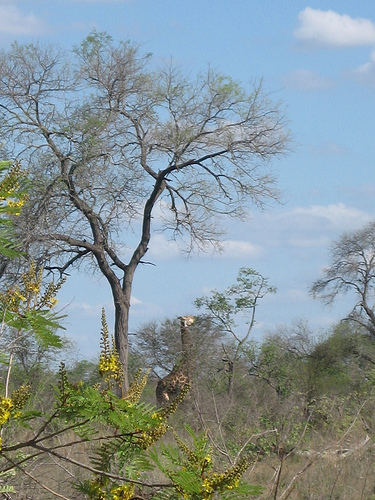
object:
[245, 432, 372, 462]
log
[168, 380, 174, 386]
spots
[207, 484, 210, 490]
flowers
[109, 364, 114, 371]
flowers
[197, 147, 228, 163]
branch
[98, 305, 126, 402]
flower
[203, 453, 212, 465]
flower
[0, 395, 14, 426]
flower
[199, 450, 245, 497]
flower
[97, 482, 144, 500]
flower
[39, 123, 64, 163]
branch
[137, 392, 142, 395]
flowers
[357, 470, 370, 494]
bushes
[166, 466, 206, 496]
leaf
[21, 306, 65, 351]
leaf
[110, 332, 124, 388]
flower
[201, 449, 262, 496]
flower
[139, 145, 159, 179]
branch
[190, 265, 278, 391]
tree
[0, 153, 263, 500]
tree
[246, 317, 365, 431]
tree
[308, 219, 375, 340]
tree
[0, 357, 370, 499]
grass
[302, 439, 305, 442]
weeds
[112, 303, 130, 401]
trunk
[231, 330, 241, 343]
branch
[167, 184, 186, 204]
branch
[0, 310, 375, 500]
brush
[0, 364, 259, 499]
tree branch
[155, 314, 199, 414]
giraffe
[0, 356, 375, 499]
field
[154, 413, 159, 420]
wildflowers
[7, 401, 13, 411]
wildflowers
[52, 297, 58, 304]
wildflowers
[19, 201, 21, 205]
wildflowers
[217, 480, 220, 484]
wildflowers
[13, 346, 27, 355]
trees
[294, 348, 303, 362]
trees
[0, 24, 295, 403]
tree